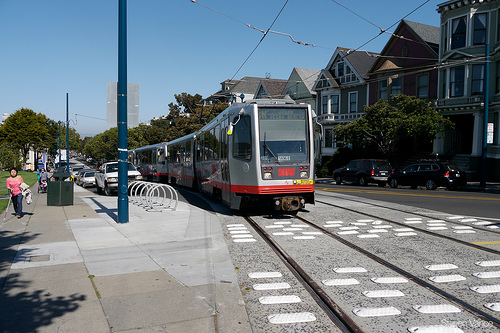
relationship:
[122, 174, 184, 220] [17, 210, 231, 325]
bike rack on sidewalk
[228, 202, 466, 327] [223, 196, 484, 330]
white rectangles on road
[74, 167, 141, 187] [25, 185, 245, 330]
cars parked beside sidewalk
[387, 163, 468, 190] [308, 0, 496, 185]
black car parked in front of houses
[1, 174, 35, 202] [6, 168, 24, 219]
pink shirt of lady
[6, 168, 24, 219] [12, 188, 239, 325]
lady walking down sidewalk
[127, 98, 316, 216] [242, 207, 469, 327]
car stopped on tracks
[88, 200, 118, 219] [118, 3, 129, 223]
shadow of blue pole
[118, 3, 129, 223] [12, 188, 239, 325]
blue pole on sidewalk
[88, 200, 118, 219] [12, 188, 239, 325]
shadow on sidewalk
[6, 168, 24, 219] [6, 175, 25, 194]
lady in pink shirt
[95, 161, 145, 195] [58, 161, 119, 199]
truck parked at curb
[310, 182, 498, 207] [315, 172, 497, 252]
yellow line on street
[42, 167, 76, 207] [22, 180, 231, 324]
garbage can on sidewalk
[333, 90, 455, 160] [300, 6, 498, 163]
tree in front of houses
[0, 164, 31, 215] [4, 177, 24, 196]
lady wearing pink shirt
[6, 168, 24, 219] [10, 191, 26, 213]
lady wearing blue jeans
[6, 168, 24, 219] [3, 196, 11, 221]
lady using cane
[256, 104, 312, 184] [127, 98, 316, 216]
front window of car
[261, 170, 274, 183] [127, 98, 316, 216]
left headlight of car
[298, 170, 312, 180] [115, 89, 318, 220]
right headlight of trolley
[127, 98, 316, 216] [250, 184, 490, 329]
car driving on tracks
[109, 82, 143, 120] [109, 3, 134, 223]
sign on blue pole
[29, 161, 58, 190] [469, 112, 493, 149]
signs on pole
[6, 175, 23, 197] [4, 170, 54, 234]
pink shirt on woman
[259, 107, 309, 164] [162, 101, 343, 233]
front window on train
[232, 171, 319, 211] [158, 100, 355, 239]
bumper on car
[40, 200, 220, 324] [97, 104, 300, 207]
sidewalk by train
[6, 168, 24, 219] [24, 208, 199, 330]
lady on sidewalk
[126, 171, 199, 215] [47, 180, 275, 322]
rack on sidewalk